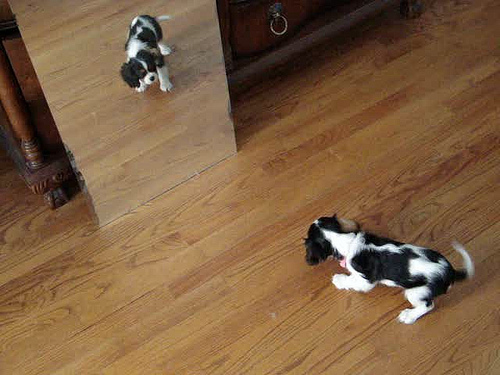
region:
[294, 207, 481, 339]
black and white puppy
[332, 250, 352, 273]
orange tag on collar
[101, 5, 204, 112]
reflection of puppy in mirror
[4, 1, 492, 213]
large wooden clothes dresser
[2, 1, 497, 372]
solid wood plank floor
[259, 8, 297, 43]
gold pull handle on dresser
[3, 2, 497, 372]
puppy looking at his reflection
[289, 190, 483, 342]
puppy with floppy ears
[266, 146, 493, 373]
puppy on wooden floor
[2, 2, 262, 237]
large mirror on floor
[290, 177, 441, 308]
dog on the ground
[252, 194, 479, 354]
black and white dog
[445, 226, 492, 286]
tail of the dog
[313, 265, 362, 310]
paw of the dog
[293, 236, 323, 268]
ear of the dog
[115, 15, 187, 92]
dog in the mirror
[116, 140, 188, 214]
glass next to the dog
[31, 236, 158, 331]
light and dark brown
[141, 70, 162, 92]
nose of the dog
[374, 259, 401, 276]
black fur on dog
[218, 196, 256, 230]
part of a floor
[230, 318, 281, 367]
part of a floor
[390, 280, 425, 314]
part of a thigh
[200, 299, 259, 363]
part of a floor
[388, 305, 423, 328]
edge of a paw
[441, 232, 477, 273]
tip of a tail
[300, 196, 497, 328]
a black and white puppy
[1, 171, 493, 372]
a hard wood floor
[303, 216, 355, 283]
a puppy with a pink collar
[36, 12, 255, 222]
a puppies reflection in a mirror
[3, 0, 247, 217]
a large unframed mirror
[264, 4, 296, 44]
a metal ring pull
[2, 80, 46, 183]
a polished wood post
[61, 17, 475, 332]
a puppy staring at its reflection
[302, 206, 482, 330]
a dog wagging its tail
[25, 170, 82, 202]
some decorative wood work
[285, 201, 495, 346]
dog is black and white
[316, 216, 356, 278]
dog has black ears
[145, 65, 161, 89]
dog has black nose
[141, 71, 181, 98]
white patch on face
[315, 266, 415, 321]
dog has white paws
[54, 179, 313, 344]
floor is brown wood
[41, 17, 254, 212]
dog looks at reflection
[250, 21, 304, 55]
drawer handle next to mirror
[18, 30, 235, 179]
mirror leans on table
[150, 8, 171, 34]
dog has white tail